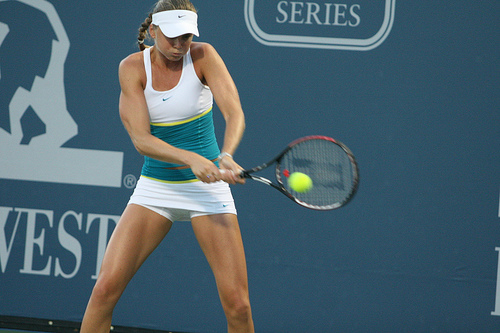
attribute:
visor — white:
[146, 8, 200, 37]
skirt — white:
[129, 172, 238, 220]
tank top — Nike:
[142, 47, 218, 182]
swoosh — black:
[173, 13, 190, 21]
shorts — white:
[129, 172, 239, 220]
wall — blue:
[0, 0, 498, 330]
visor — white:
[133, 49, 202, 80]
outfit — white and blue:
[121, 135, 234, 233]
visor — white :
[158, 99, 193, 122]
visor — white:
[163, 49, 184, 64]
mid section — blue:
[134, 118, 218, 193]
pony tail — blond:
[106, 49, 139, 73]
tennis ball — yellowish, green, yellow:
[285, 164, 318, 200]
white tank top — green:
[127, 44, 231, 167]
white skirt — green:
[130, 162, 239, 218]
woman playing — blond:
[105, 2, 261, 318]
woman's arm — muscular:
[115, 57, 210, 180]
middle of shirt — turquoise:
[131, 119, 224, 182]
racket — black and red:
[212, 126, 378, 239]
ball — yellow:
[274, 168, 319, 196]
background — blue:
[3, 3, 495, 331]